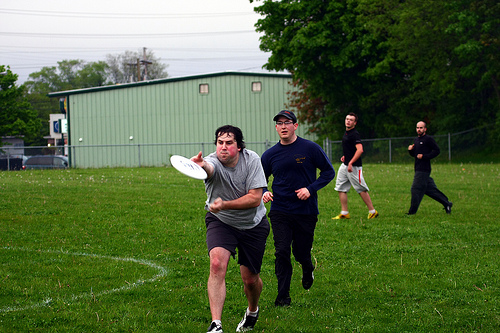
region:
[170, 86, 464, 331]
Four men in the photo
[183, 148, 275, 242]
Man in the foreground is wearing a gray shirt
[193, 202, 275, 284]
Man is wearing dark gray shorts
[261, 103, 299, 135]
Man is wearing eyeglasses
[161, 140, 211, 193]
A flying disc in the foreground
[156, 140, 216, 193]
The flying disc is white in color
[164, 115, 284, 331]
Man is trying to grab the flying disc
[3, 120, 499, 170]
A fence in the background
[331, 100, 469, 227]
Two men in the background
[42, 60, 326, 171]
A light green colored building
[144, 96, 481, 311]
these men are playing frisbee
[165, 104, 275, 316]
this guy is throwing a frisbee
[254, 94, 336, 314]
this man is waiting for the frisbee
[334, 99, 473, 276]
these guys are in the background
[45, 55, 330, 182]
a green building in the area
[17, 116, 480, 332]
the players are on a field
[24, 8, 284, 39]
the sky is gray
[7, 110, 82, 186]
a car parked in the distance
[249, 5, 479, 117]
trees in the environment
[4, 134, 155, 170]
a fence around the field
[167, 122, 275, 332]
A man is throwing a frisbee.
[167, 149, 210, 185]
The color of a frisbee is white.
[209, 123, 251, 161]
A man has black hair.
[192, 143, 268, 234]
A man is wearing a gray t-shirt.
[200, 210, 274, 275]
A man is wearing dark pants.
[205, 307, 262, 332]
a man is wearing black and white shoes.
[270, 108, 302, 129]
A man is wearing a dark cap.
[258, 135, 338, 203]
A man is wearing a blue and yellow top.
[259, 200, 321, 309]
A man is wearing dark pants.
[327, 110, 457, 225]
Two men are in the background.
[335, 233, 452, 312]
The grass is green and long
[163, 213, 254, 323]
The man is running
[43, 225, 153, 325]
The ground has lines on it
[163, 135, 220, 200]
The people are playing frisbee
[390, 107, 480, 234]
The man is in all black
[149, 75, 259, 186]
The building is in the back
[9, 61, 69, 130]
The trees are tall and green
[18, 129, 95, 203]
The van is parked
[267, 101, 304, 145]
The man has glasses on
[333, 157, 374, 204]
The man has shorts on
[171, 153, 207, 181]
a white Frisbee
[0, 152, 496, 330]
a large green field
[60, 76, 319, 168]
part of a green building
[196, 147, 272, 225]
a man's gray shirt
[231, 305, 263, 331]
a man's tennis shoe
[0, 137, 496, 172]
part of a long chain link fence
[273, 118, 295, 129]
a man's eyeglasses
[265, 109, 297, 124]
a black and red baseball cap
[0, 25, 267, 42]
a long electrical power line